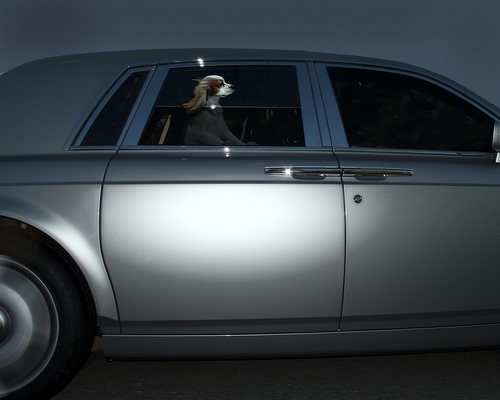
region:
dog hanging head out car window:
[175, 73, 257, 151]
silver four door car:
[5, 50, 496, 396]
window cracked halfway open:
[135, 64, 306, 149]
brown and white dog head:
[178, 73, 234, 113]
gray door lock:
[352, 192, 362, 205]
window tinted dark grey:
[324, 63, 490, 160]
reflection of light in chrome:
[281, 164, 294, 176]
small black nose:
[227, 81, 234, 91]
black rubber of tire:
[4, 225, 89, 395]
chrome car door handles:
[265, 163, 410, 182]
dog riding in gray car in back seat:
[60, 38, 496, 155]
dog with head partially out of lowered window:
[132, 55, 307, 142]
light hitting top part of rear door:
[70, 166, 376, 291]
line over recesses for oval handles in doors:
[260, 165, 411, 180]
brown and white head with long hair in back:
[180, 71, 232, 107]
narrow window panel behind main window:
[62, 57, 302, 147]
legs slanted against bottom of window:
[180, 105, 242, 145]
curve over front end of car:
[312, 45, 497, 145]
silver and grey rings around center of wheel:
[0, 215, 60, 395]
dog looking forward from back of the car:
[114, 60, 316, 177]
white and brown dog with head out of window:
[185, 71, 236, 109]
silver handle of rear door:
[260, 165, 343, 179]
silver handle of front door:
[342, 167, 412, 179]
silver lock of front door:
[353, 192, 363, 204]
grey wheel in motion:
[0, 260, 54, 380]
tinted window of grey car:
[328, 62, 493, 152]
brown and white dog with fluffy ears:
[183, 74, 238, 110]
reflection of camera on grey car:
[184, 53, 219, 68]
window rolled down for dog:
[147, 72, 298, 149]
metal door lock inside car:
[289, 134, 300, 146]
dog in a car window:
[158, 69, 253, 155]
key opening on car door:
[348, 188, 370, 209]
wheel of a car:
[0, 235, 82, 398]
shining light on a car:
[118, 185, 321, 257]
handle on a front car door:
[345, 155, 400, 190]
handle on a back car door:
[278, 158, 335, 196]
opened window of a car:
[161, 94, 301, 144]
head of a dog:
[184, 70, 240, 102]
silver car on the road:
[3, 33, 498, 396]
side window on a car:
[326, 59, 498, 165]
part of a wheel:
[83, 336, 130, 357]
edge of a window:
[228, 162, 234, 173]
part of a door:
[315, 136, 320, 249]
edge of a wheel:
[45, 320, 70, 351]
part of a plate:
[47, 323, 72, 332]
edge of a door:
[265, 209, 285, 239]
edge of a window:
[353, 92, 360, 104]